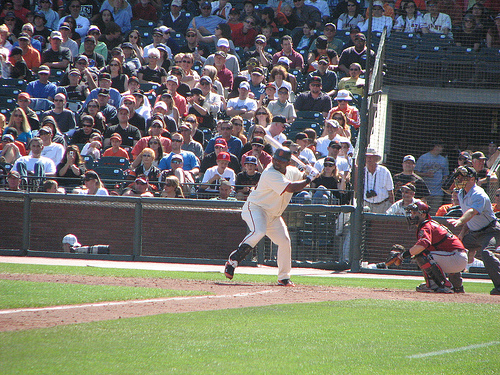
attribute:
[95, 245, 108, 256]
lens — zoom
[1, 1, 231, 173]
fans — watching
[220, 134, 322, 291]
batter — hitting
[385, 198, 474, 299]
catcher — crouched, catching, crouching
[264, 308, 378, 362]
grass — green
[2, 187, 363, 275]
fence — green